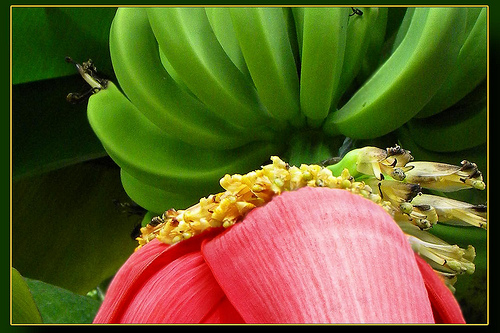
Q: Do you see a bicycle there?
A: No, there are no bicycles.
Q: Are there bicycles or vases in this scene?
A: No, there are no bicycles or vases.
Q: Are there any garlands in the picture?
A: No, there are no garlands.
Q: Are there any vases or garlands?
A: No, there are no garlands or vases.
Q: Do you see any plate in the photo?
A: No, there are no plates.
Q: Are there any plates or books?
A: No, there are no plates or books.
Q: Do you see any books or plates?
A: No, there are no plates or books.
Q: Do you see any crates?
A: No, there are no crates.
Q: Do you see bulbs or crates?
A: No, there are no crates or bulbs.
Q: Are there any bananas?
A: Yes, there are bananas.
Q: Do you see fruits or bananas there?
A: Yes, there are bananas.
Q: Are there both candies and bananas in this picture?
A: No, there are bananas but no candies.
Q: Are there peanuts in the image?
A: No, there are no peanuts.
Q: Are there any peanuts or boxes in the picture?
A: No, there are no peanuts or boxes.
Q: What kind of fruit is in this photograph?
A: The fruit is bananas.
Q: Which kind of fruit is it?
A: The fruits are bananas.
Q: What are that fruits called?
A: These are bananas.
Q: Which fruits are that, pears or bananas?
A: These are bananas.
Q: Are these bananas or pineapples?
A: These are bananas.